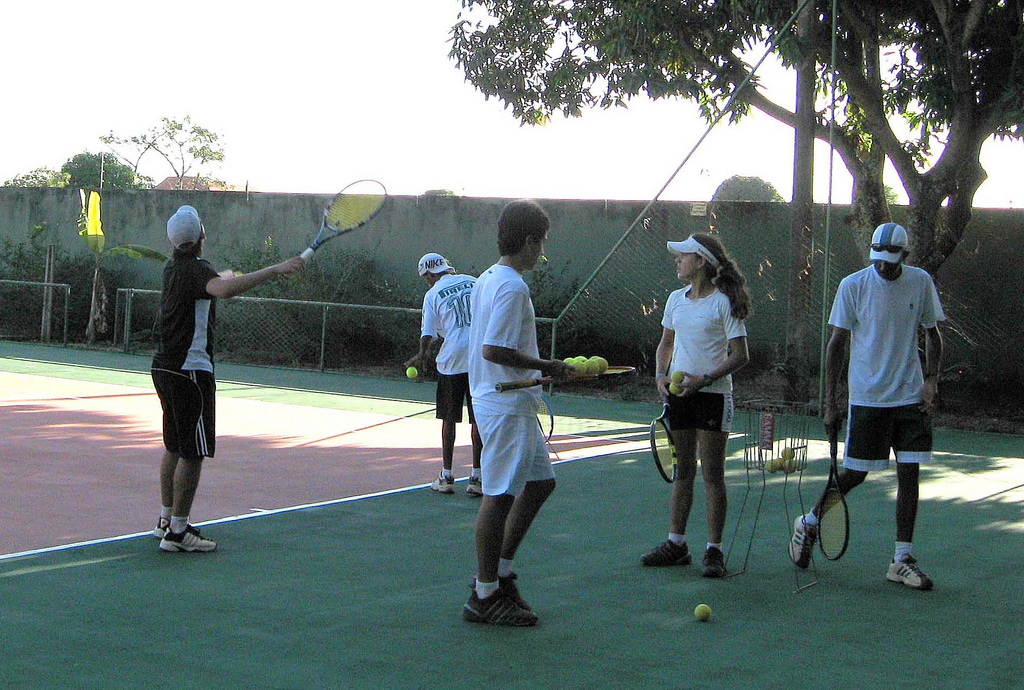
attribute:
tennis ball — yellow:
[677, 577, 736, 638]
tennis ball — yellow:
[677, 592, 732, 636]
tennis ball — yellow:
[660, 361, 700, 400]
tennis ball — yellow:
[569, 338, 622, 386]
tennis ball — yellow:
[552, 342, 624, 382]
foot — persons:
[156, 515, 221, 554]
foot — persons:
[457, 582, 540, 621]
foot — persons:
[429, 463, 455, 494]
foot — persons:
[640, 532, 695, 582]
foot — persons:
[154, 500, 226, 567]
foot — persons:
[426, 463, 457, 505]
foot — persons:
[454, 461, 496, 500]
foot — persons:
[463, 579, 535, 632]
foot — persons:
[638, 521, 706, 576]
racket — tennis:
[305, 160, 392, 271]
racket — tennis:
[500, 361, 641, 390]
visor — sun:
[662, 229, 725, 282]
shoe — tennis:
[642, 523, 695, 573]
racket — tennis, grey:
[307, 176, 392, 261]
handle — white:
[271, 238, 323, 282]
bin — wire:
[735, 405, 822, 568]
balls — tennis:
[763, 439, 800, 478]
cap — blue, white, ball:
[867, 214, 919, 275]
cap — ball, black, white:
[413, 249, 461, 286]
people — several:
[152, 180, 958, 636]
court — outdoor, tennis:
[14, 353, 1011, 682]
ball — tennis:
[690, 595, 717, 628]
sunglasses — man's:
[863, 232, 905, 261]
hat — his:
[865, 214, 911, 269]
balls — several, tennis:
[562, 351, 608, 373]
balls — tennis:
[761, 439, 809, 474]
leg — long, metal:
[785, 487, 825, 565]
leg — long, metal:
[725, 456, 775, 578]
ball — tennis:
[403, 361, 419, 379]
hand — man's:
[405, 350, 432, 372]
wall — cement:
[3, 173, 1008, 422]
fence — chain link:
[24, 269, 589, 384]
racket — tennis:
[288, 167, 395, 247]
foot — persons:
[467, 573, 534, 638]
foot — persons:
[640, 530, 692, 572]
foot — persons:
[696, 538, 735, 580]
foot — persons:
[779, 493, 827, 574]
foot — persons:
[880, 534, 930, 589]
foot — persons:
[779, 502, 819, 572]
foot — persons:
[686, 539, 736, 587]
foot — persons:
[636, 532, 695, 576]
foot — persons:
[463, 562, 543, 630]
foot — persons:
[169, 521, 196, 550]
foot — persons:
[459, 564, 539, 632]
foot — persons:
[640, 525, 686, 577]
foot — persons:
[696, 530, 736, 578]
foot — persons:
[791, 506, 828, 563]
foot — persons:
[876, 530, 954, 610]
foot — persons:
[787, 502, 829, 582]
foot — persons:
[686, 538, 730, 593]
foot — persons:
[638, 534, 695, 571]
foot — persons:
[457, 577, 557, 630]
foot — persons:
[152, 519, 230, 558]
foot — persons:
[456, 569, 545, 639]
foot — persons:
[640, 521, 690, 578]